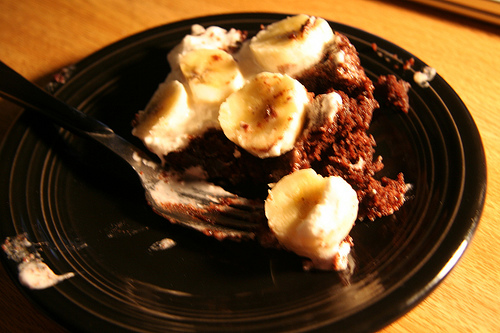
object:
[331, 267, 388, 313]
light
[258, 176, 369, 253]
banana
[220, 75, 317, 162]
banana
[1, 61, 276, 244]
fork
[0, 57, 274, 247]
spon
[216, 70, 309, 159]
potato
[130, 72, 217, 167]
banana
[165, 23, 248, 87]
banana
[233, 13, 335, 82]
banana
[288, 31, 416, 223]
cake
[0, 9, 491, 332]
ripples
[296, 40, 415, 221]
meat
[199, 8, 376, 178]
jersey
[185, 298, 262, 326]
black ripples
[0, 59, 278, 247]
spoon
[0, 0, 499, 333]
table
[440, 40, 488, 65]
ground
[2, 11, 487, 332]
plate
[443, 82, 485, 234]
edge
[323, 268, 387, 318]
reflection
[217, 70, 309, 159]
banana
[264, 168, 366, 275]
potato